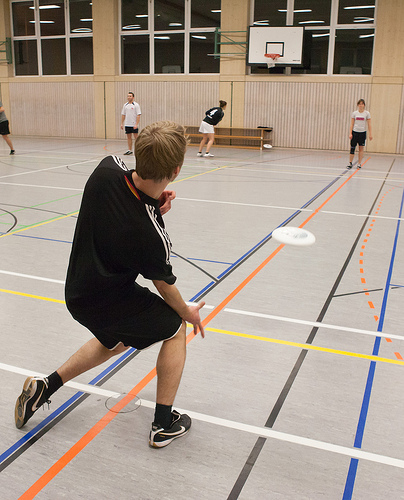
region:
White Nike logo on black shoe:
[25, 379, 46, 416]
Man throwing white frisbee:
[13, 123, 207, 451]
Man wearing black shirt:
[10, 118, 209, 451]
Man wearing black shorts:
[9, 117, 210, 449]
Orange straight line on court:
[8, 145, 373, 496]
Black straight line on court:
[193, 152, 396, 498]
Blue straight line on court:
[0, 149, 362, 475]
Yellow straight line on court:
[0, 242, 402, 368]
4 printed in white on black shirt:
[206, 106, 220, 118]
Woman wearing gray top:
[341, 92, 374, 173]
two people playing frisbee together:
[13, 97, 374, 439]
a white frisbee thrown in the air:
[270, 225, 314, 249]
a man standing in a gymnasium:
[119, 92, 140, 155]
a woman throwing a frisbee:
[195, 97, 272, 158]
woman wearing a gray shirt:
[353, 108, 368, 130]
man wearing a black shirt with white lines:
[64, 153, 177, 306]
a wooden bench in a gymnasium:
[182, 125, 273, 151]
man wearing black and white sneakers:
[15, 377, 192, 447]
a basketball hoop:
[250, 28, 301, 70]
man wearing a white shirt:
[122, 101, 141, 128]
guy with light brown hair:
[9, 108, 224, 456]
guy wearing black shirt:
[4, 114, 224, 452]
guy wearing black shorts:
[9, 105, 210, 450]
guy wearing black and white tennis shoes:
[10, 98, 203, 451]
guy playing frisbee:
[2, 113, 321, 495]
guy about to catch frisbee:
[2, 110, 334, 458]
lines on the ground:
[281, 171, 400, 214]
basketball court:
[246, 24, 307, 71]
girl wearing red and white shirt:
[342, 97, 376, 172]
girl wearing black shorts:
[340, 96, 378, 173]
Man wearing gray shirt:
[117, 89, 142, 153]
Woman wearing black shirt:
[192, 94, 230, 159]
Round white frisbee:
[270, 218, 316, 247]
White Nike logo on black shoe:
[155, 419, 187, 442]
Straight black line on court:
[202, 155, 397, 498]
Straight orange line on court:
[17, 153, 375, 499]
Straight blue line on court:
[0, 149, 364, 461]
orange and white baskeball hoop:
[262, 51, 282, 68]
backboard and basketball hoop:
[244, 23, 305, 69]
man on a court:
[12, 120, 221, 459]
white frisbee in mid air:
[270, 222, 317, 250]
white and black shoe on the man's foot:
[10, 374, 46, 429]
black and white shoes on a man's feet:
[12, 374, 192, 450]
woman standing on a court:
[344, 98, 375, 171]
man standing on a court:
[118, 91, 142, 155]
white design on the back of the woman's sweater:
[210, 108, 220, 116]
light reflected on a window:
[122, 21, 143, 29]